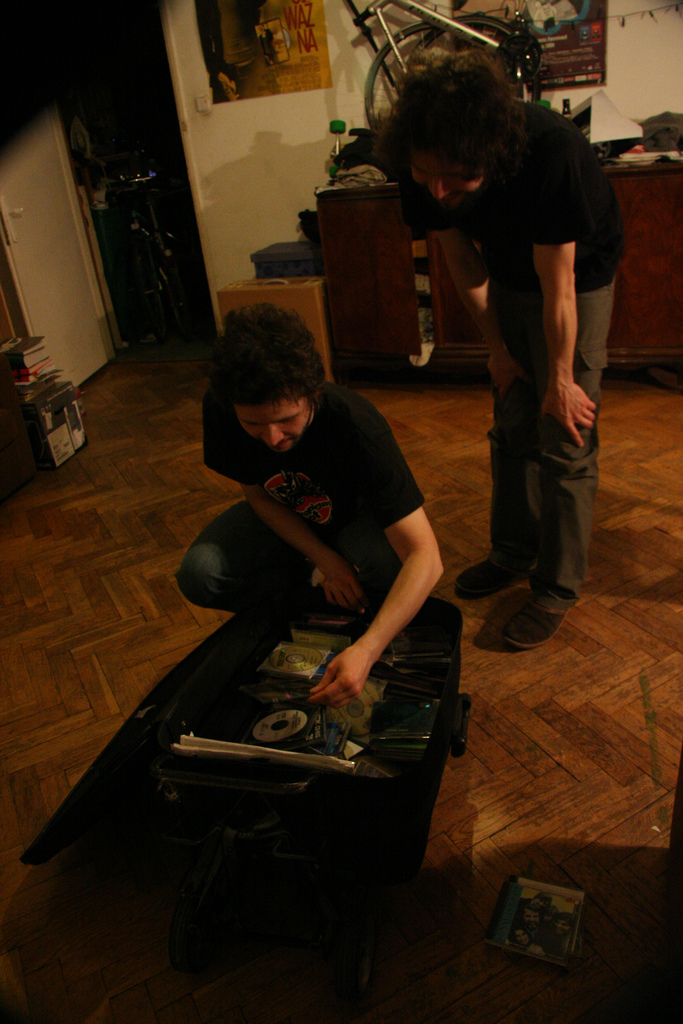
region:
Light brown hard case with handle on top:
[215, 273, 339, 381]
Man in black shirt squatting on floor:
[173, 296, 452, 709]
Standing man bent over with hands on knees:
[372, 45, 630, 651]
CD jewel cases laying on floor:
[481, 867, 593, 971]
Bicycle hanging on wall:
[341, 0, 546, 136]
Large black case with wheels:
[19, 580, 480, 998]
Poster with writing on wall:
[192, 0, 337, 104]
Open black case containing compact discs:
[20, 584, 478, 1008]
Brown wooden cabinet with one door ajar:
[315, 160, 680, 389]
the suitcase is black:
[19, 589, 473, 1001]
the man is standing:
[369, 43, 621, 650]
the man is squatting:
[161, 296, 442, 706]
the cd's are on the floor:
[482, 865, 587, 970]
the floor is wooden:
[1, 357, 675, 1017]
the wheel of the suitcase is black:
[320, 921, 377, 1003]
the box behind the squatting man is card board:
[212, 272, 337, 382]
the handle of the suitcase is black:
[447, 688, 469, 757]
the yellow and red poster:
[190, 0, 340, 105]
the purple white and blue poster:
[444, 0, 611, 93]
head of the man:
[410, 93, 504, 187]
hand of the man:
[307, 628, 372, 704]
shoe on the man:
[486, 607, 545, 642]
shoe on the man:
[466, 571, 508, 596]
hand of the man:
[539, 364, 589, 437]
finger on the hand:
[557, 419, 593, 443]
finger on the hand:
[304, 687, 327, 705]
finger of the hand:
[317, 664, 336, 679]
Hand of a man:
[305, 649, 373, 713]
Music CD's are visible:
[479, 863, 591, 972]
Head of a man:
[204, 297, 323, 462]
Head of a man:
[377, 50, 523, 223]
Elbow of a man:
[411, 539, 450, 586]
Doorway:
[24, 5, 232, 356]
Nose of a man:
[259, 425, 286, 449]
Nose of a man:
[426, 178, 448, 202]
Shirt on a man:
[384, 92, 637, 298]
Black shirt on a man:
[397, 89, 629, 302]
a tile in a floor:
[562, 685, 672, 795]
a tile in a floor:
[456, 815, 548, 903]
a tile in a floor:
[596, 517, 657, 582]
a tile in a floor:
[604, 481, 664, 543]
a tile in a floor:
[418, 507, 486, 558]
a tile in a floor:
[584, 783, 678, 874]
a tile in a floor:
[607, 474, 666, 532]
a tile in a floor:
[452, 649, 534, 689]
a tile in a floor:
[629, 451, 679, 488]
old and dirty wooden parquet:
[510, 753, 653, 870]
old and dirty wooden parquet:
[584, 596, 678, 696]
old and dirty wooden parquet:
[611, 490, 682, 595]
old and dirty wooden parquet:
[12, 650, 124, 749]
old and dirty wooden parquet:
[8, 566, 89, 638]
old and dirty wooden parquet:
[57, 482, 186, 579]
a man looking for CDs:
[154, 324, 476, 765]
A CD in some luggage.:
[242, 708, 311, 746]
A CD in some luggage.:
[253, 636, 315, 677]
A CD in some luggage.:
[367, 690, 433, 734]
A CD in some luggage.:
[370, 731, 429, 754]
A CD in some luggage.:
[376, 752, 416, 765]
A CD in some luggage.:
[329, 674, 370, 723]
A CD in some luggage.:
[396, 647, 441, 671]